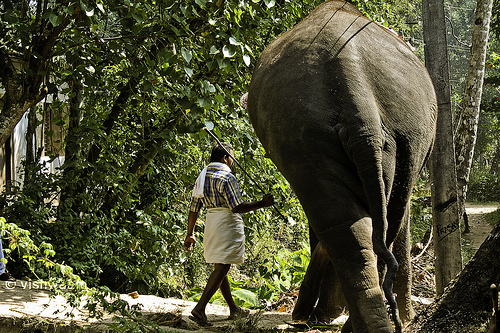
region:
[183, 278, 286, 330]
he has on sandals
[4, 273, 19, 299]
copyright sign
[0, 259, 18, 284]
person's shoe on the left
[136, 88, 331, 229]
he is carrying a stick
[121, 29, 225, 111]
the leaves are green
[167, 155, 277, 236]
he has on a striped shirt on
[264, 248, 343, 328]
the sun is shining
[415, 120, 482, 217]
trees all around the elephant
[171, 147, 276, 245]
boy is walking away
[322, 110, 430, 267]
tail of the elephant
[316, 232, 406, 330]
back foot of the elephant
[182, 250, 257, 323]
legs of the person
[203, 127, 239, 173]
head of the person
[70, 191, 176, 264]
leaves next to the person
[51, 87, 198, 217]
trees next to the person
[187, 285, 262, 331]
feet on the ground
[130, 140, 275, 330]
man holding a stick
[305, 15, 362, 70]
light hitting the elephant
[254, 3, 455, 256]
elephant not facing the camera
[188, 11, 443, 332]
person guiding an elephant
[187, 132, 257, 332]
person in a plaid shirt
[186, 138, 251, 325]
walking person in white skirt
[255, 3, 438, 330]
backside of an elephant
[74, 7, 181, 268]
branches and green foliage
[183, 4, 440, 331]
elephand and person side by side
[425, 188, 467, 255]
writing on a tree trunk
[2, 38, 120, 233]
white building behind trees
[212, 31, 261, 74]
green leaves reflecting sunlight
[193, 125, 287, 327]
person holding a stick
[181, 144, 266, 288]
this is a man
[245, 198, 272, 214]
the man is light skinned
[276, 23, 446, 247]
this is a elephant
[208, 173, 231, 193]
this is a shirt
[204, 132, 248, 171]
this is a stick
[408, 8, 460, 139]
this is a pole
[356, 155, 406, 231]
this is the tail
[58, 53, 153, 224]
this is a tree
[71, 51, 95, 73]
the leaves are green in color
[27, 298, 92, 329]
this is the ground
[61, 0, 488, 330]
a man controlling an elephant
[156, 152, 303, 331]
he his wearing a white cloth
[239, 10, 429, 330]
the elephant is large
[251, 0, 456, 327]
its brown in colour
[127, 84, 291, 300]
the man is holding a stick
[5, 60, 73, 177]
a house is near the trees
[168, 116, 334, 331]
the man is wearing sandles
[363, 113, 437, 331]
the tail is long and curved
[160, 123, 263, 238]
the man has a white scarf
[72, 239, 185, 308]
he floweris red in colour